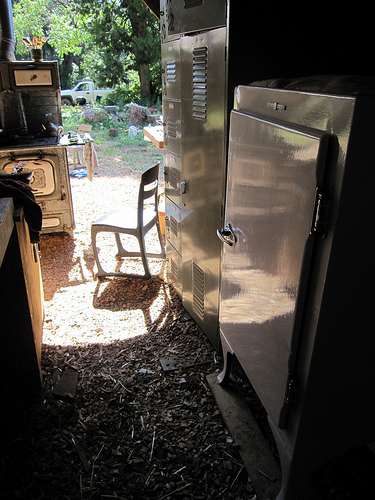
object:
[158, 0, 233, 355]
cabinets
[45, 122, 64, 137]
pot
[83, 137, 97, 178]
cloth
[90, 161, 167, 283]
chair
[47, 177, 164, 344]
sun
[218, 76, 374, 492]
containers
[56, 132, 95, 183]
table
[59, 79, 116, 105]
truck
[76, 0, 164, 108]
tree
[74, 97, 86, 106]
grill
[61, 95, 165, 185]
yard